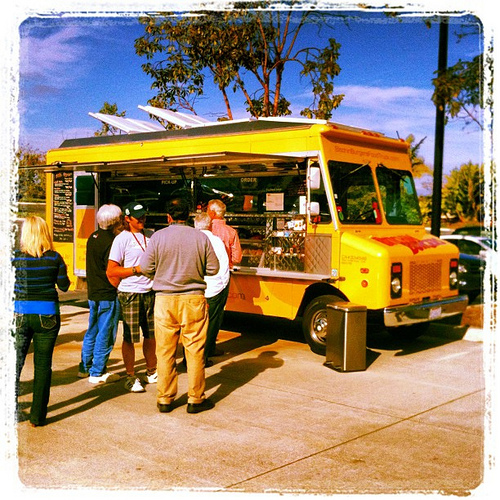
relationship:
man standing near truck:
[157, 206, 215, 405] [52, 136, 476, 323]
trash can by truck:
[318, 293, 376, 379] [52, 136, 476, 323]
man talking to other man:
[157, 206, 215, 405] [115, 202, 152, 386]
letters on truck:
[376, 223, 457, 262] [52, 136, 476, 323]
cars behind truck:
[464, 230, 486, 279] [52, 136, 476, 323]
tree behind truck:
[182, 32, 265, 79] [52, 136, 476, 323]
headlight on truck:
[387, 268, 405, 299] [52, 136, 476, 323]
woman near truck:
[17, 210, 72, 427] [52, 136, 476, 323]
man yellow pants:
[157, 206, 215, 405] [156, 299, 206, 384]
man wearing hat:
[115, 202, 152, 386] [126, 197, 150, 224]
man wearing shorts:
[115, 202, 152, 386] [118, 290, 151, 335]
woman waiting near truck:
[17, 210, 72, 427] [52, 136, 476, 323]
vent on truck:
[142, 89, 198, 130] [52, 136, 476, 323]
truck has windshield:
[52, 136, 476, 323] [333, 157, 410, 209]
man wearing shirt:
[157, 206, 215, 405] [157, 234, 202, 272]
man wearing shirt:
[115, 202, 152, 386] [119, 236, 146, 268]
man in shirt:
[87, 208, 116, 301] [89, 243, 110, 283]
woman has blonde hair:
[17, 224, 70, 395] [18, 217, 58, 259]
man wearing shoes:
[157, 206, 215, 405] [155, 395, 206, 416]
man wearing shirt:
[207, 199, 239, 244] [221, 226, 244, 251]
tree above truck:
[182, 32, 265, 79] [52, 136, 476, 323]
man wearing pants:
[157, 206, 215, 405] [156, 299, 206, 384]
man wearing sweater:
[157, 206, 215, 405] [157, 234, 202, 272]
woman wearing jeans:
[17, 224, 70, 395] [21, 317, 58, 359]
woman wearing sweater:
[17, 224, 70, 395] [23, 251, 59, 286]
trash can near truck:
[318, 293, 376, 379] [52, 136, 476, 323]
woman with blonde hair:
[17, 224, 70, 395] [18, 217, 58, 259]